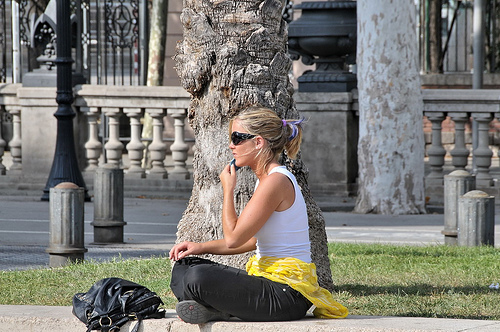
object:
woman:
[169, 108, 318, 324]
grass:
[1, 242, 499, 320]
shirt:
[254, 165, 312, 263]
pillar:
[7, 105, 21, 172]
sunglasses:
[231, 131, 257, 146]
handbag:
[71, 277, 165, 332]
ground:
[0, 198, 499, 331]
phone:
[230, 159, 240, 172]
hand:
[219, 163, 236, 189]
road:
[0, 199, 499, 270]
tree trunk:
[170, 0, 336, 294]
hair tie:
[282, 115, 305, 141]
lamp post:
[40, 0, 91, 201]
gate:
[79, 0, 149, 87]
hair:
[229, 108, 310, 176]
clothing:
[244, 254, 350, 318]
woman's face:
[229, 120, 253, 167]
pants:
[170, 256, 313, 322]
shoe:
[176, 300, 231, 323]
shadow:
[333, 283, 499, 297]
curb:
[0, 305, 500, 331]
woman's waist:
[256, 255, 312, 275]